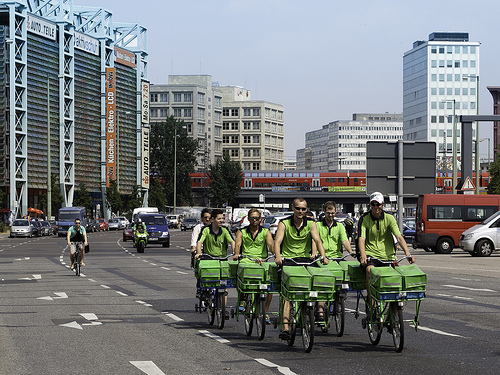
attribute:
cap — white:
[367, 193, 391, 210]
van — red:
[410, 193, 499, 255]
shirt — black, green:
[357, 216, 406, 268]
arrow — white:
[58, 310, 104, 336]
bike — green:
[283, 292, 329, 356]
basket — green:
[281, 264, 345, 300]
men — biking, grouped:
[187, 190, 434, 356]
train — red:
[185, 168, 370, 192]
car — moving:
[136, 207, 178, 249]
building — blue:
[9, 6, 87, 226]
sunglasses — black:
[293, 203, 314, 217]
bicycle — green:
[276, 301, 312, 354]